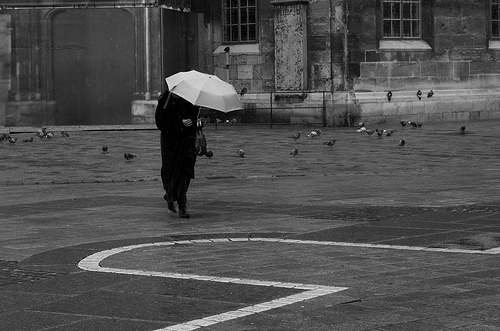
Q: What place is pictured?
A: It is a road.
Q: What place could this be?
A: It is a road.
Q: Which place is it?
A: It is a road.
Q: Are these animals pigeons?
A: No, there are both pigeons and birds.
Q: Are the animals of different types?
A: Yes, they are pigeons and birds.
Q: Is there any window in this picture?
A: Yes, there is a window.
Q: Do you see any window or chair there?
A: Yes, there is a window.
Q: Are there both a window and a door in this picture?
A: Yes, there are both a window and a door.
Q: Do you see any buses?
A: No, there are no buses.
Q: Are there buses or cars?
A: No, there are no buses or cars.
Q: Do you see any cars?
A: No, there are no cars.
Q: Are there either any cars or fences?
A: No, there are no cars or fences.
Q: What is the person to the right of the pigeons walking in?
A: The person is walking in the rain.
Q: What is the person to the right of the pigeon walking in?
A: The person is walking in the rain.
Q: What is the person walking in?
A: The person is walking in the rain.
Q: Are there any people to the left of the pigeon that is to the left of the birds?
A: Yes, there is a person to the left of the pigeon.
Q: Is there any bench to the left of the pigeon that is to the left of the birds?
A: No, there is a person to the left of the pigeon.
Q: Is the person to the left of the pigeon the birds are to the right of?
A: Yes, the person is to the left of the pigeon.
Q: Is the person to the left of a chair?
A: No, the person is to the left of the pigeon.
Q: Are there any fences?
A: No, there are no fences.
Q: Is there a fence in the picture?
A: No, there are no fences.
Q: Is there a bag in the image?
A: Yes, there is a bag.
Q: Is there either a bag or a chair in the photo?
A: Yes, there is a bag.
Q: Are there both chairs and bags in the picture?
A: No, there is a bag but no chairs.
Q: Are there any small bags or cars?
A: Yes, there is a small bag.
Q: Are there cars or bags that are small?
A: Yes, the bag is small.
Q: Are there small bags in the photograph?
A: Yes, there is a small bag.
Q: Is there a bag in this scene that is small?
A: Yes, there is a bag that is small.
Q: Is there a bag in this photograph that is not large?
A: Yes, there is a small bag.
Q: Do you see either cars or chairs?
A: No, there are no cars or chairs.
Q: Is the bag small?
A: Yes, the bag is small.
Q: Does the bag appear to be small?
A: Yes, the bag is small.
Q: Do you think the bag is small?
A: Yes, the bag is small.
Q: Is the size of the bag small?
A: Yes, the bag is small.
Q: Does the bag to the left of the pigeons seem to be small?
A: Yes, the bag is small.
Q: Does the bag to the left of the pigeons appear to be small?
A: Yes, the bag is small.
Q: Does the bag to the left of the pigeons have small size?
A: Yes, the bag is small.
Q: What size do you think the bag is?
A: The bag is small.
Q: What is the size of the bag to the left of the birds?
A: The bag is small.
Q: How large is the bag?
A: The bag is small.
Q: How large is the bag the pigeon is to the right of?
A: The bag is small.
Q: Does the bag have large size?
A: No, the bag is small.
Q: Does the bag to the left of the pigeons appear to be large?
A: No, the bag is small.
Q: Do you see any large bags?
A: No, there is a bag but it is small.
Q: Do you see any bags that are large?
A: No, there is a bag but it is small.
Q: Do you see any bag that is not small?
A: No, there is a bag but it is small.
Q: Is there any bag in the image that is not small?
A: No, there is a bag but it is small.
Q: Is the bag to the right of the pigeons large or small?
A: The bag is small.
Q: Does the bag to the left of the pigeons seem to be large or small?
A: The bag is small.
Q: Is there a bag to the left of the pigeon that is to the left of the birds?
A: Yes, there is a bag to the left of the pigeon.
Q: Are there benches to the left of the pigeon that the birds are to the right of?
A: No, there is a bag to the left of the pigeon.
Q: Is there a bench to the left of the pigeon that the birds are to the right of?
A: No, there is a bag to the left of the pigeon.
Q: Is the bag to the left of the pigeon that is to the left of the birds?
A: Yes, the bag is to the left of the pigeon.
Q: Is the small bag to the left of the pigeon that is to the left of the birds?
A: Yes, the bag is to the left of the pigeon.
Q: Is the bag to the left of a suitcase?
A: No, the bag is to the left of the pigeon.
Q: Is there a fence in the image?
A: No, there are no fences.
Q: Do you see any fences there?
A: No, there are no fences.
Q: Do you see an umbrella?
A: Yes, there is an umbrella.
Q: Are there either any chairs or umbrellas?
A: Yes, there is an umbrella.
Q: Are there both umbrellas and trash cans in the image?
A: No, there is an umbrella but no trash cans.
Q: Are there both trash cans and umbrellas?
A: No, there is an umbrella but no trash cans.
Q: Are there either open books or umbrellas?
A: Yes, there is an open umbrella.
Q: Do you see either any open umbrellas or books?
A: Yes, there is an open umbrella.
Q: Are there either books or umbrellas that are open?
A: Yes, the umbrella is open.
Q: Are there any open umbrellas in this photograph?
A: Yes, there is an open umbrella.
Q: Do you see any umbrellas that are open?
A: Yes, there is an umbrella that is open.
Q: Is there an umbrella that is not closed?
A: Yes, there is a open umbrella.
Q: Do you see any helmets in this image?
A: No, there are no helmets.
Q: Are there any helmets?
A: No, there are no helmets.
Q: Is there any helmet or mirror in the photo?
A: No, there are no helmets or mirrors.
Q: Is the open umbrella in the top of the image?
A: Yes, the umbrella is in the top of the image.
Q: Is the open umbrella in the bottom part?
A: No, the umbrella is in the top of the image.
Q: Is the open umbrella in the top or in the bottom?
A: The umbrella is in the top of the image.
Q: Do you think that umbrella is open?
A: Yes, the umbrella is open.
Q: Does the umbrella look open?
A: Yes, the umbrella is open.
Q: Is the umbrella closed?
A: No, the umbrella is open.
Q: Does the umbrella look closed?
A: No, the umbrella is open.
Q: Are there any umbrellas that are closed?
A: No, there is an umbrella but it is open.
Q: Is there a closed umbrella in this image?
A: No, there is an umbrella but it is open.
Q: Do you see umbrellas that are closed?
A: No, there is an umbrella but it is open.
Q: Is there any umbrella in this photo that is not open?
A: No, there is an umbrella but it is open.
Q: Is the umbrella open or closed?
A: The umbrella is open.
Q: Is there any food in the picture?
A: Yes, there is food.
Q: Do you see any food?
A: Yes, there is food.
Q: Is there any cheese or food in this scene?
A: Yes, there is food.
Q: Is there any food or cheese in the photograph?
A: Yes, there is food.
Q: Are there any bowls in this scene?
A: No, there are no bowls.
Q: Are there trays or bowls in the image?
A: No, there are no bowls or trays.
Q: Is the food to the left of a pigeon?
A: Yes, the food is to the left of a pigeon.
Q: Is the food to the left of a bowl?
A: No, the food is to the left of a pigeon.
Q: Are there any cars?
A: No, there are no cars.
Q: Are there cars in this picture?
A: No, there are no cars.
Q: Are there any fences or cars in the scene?
A: No, there are no cars or fences.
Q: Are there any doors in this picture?
A: Yes, there is a door.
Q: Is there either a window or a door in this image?
A: Yes, there is a door.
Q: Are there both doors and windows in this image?
A: Yes, there are both a door and a window.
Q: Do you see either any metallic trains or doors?
A: Yes, there is a metal door.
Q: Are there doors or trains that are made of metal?
A: Yes, the door is made of metal.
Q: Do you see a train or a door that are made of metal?
A: Yes, the door is made of metal.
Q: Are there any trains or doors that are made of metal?
A: Yes, the door is made of metal.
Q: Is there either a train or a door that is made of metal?
A: Yes, the door is made of metal.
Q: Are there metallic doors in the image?
A: Yes, there is a metal door.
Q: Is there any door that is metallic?
A: Yes, there is a door that is metallic.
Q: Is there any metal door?
A: Yes, there is a door that is made of metal.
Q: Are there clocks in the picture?
A: No, there are no clocks.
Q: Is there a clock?
A: No, there are no clocks.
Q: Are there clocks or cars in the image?
A: No, there are no clocks or cars.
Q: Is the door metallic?
A: Yes, the door is metallic.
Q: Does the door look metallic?
A: Yes, the door is metallic.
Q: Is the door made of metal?
A: Yes, the door is made of metal.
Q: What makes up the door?
A: The door is made of metal.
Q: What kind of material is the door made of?
A: The door is made of metal.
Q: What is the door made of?
A: The door is made of metal.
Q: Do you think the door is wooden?
A: No, the door is metallic.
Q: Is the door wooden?
A: No, the door is metallic.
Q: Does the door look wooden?
A: No, the door is metallic.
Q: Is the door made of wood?
A: No, the door is made of metal.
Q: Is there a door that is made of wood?
A: No, there is a door but it is made of metal.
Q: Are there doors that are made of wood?
A: No, there is a door but it is made of metal.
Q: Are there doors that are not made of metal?
A: No, there is a door but it is made of metal.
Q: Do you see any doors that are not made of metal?
A: No, there is a door but it is made of metal.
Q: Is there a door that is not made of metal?
A: No, there is a door but it is made of metal.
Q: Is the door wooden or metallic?
A: The door is metallic.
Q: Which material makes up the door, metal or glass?
A: The door is made of metal.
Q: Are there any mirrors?
A: No, there are no mirrors.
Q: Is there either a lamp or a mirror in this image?
A: No, there are no mirrors or lamps.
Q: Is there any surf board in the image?
A: No, there are no surfboards.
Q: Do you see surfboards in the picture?
A: No, there are no surfboards.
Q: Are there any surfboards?
A: No, there are no surfboards.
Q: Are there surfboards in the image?
A: No, there are no surfboards.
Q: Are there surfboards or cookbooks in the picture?
A: No, there are no surfboards or cookbooks.